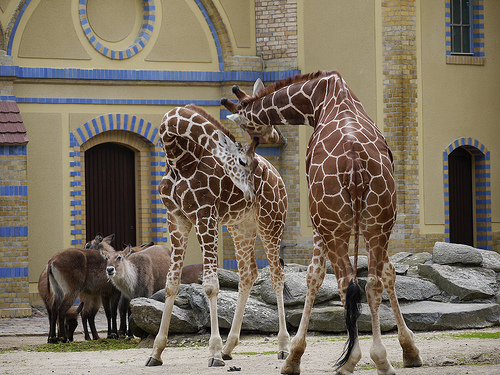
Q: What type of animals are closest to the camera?
A: Giraffes.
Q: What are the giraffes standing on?
A: Dirt.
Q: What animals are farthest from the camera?
A: Deer.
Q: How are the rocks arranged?
A: Stacked.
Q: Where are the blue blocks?
A: On the building.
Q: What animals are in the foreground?
A: A pair of giraffe.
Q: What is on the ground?
A: Large gray rocks.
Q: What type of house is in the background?
A: A stone house.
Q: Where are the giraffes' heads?
A: Turned to the side.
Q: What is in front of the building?
A: Animals and rocks.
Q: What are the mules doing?
A: Standing around.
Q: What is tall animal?
A: Giraffe.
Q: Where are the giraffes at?
A: The zoo.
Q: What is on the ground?
A: Rocks.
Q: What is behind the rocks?
A: Three deers.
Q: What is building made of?
A: Bricks.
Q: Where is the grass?
A: Under rocks.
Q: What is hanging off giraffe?
A: Black tail.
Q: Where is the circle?
A: In the arch.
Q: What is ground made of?
A: Dirt and gravel.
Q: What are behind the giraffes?
A: Rocks.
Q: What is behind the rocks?
A: Deer.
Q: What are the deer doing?
A: Huddling together.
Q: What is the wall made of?
A: Stone.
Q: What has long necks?
A: Giraffe.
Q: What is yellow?
A: A building.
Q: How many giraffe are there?
A: Two.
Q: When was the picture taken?
A: Daytime.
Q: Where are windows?
A: On a building.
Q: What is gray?
A: Large rocks.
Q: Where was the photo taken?
A: In front of building.